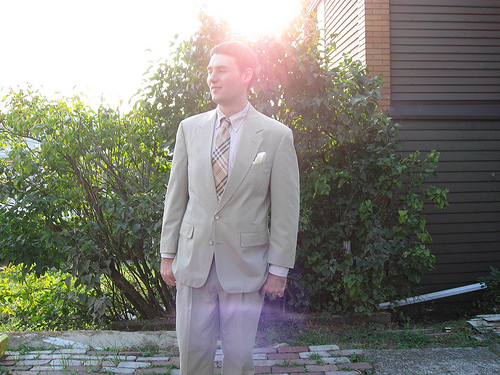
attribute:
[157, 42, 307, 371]
man — suited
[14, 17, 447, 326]
trees — green 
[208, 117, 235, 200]
burberry tie — plaid, patterned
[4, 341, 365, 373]
brick sidewalk — brike, layered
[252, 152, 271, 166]
pocket square — out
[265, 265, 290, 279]
jacket sleeve — out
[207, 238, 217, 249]
bottom button — unbuttoned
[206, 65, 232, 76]
2 eyes — set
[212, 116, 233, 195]
brown tie — tan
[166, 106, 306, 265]
suit coat — tan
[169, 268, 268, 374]
suit pants — tan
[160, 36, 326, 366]
man — red haired, young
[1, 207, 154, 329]
green yard — lush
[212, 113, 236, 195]
tie — neck, light-colored plaid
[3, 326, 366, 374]
walkway — brick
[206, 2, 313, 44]
bright sun — over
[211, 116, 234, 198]
plaid tie — worn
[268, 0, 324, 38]
rain gutter — white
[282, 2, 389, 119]
side of house — behind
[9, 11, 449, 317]
bush in yard — behind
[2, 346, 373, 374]
bricks — around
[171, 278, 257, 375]
pleated pants — khaki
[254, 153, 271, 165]
pocket square — white, wrinkled pocket 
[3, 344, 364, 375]
brick pathway — crooked brick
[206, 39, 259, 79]
brunette hairstyle — short brunette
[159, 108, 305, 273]
jacket — khaki suit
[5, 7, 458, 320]
small trees — small green